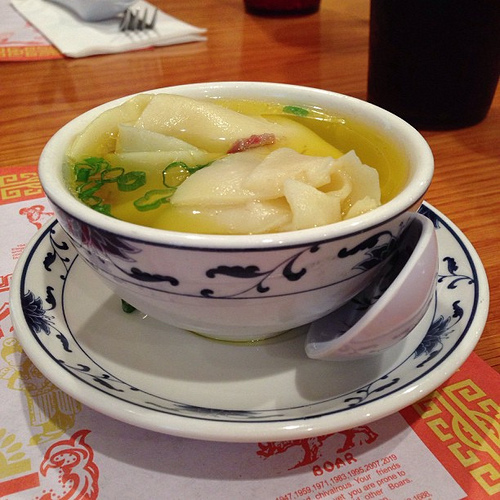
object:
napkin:
[7, 1, 207, 61]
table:
[131, 33, 329, 69]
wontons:
[171, 148, 332, 208]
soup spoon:
[307, 213, 439, 361]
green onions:
[134, 188, 176, 210]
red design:
[40, 427, 99, 498]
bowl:
[36, 81, 436, 341]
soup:
[38, 80, 432, 249]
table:
[51, 62, 108, 103]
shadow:
[78, 289, 319, 382]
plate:
[9, 201, 490, 442]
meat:
[226, 132, 273, 153]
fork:
[118, 6, 156, 31]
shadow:
[20, 345, 425, 481]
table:
[1, 1, 497, 381]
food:
[61, 86, 412, 234]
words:
[335, 457, 348, 466]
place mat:
[1, 162, 498, 497]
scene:
[0, 13, 484, 460]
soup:
[125, 110, 346, 210]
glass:
[365, 2, 499, 135]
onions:
[117, 172, 148, 192]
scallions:
[101, 166, 122, 182]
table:
[98, 51, 299, 77]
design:
[438, 257, 471, 287]